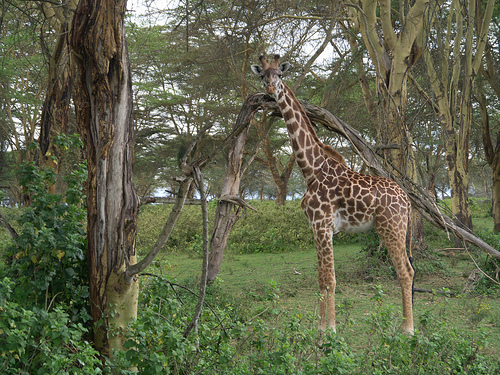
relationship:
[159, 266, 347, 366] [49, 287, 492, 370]
weeds on ground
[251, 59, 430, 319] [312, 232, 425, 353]
giraffe has legs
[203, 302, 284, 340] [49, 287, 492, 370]
sticks all ground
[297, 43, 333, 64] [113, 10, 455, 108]
clouds in sky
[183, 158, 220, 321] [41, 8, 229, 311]
branch sticking from tree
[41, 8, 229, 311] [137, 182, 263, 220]
tree has branch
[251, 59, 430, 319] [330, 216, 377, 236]
giraffe has stomach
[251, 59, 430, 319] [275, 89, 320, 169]
giraffe has neck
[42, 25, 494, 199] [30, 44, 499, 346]
forest i picture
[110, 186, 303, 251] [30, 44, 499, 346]
bushes in picture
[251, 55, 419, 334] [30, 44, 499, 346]
giraffe in picture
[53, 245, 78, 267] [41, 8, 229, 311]
fruits on tree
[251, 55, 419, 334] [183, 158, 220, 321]
giraffe near branch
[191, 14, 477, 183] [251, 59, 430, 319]
trees behind giraffe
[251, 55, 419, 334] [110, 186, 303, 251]
giraffe near bushes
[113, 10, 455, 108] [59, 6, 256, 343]
sky behind trees